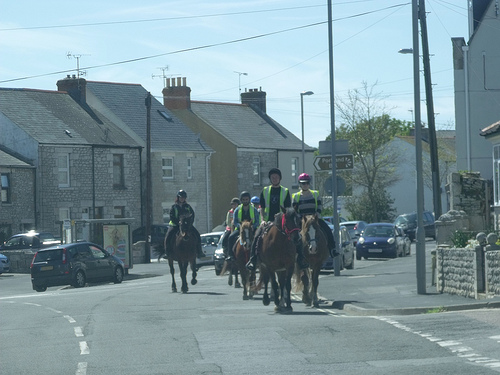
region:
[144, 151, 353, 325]
people riding horses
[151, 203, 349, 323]
horses walking down the road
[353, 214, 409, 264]
car on the side of the street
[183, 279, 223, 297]
shadow from the horse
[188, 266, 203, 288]
back leg is in the air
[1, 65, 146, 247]
the building is made of stone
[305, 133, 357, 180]
signs on a pole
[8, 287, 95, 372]
white dotted line on the street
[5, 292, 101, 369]
line is curving around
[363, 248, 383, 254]
license plate on front of the vehicle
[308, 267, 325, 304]
leg of a horse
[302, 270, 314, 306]
leg of a horse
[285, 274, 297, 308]
leg of a horse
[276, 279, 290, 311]
leg of a horse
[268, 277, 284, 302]
leg of a horse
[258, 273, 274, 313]
leg of a horse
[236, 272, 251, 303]
leg of a horse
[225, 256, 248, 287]
leg of a horse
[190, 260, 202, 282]
leg of a horse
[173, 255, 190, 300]
leg of a horse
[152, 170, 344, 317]
men riding on horses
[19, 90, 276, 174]
houses in the pack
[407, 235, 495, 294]
brick wall on side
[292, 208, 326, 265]
head of the horse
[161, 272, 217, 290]
feet of the horse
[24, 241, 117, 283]
back of the car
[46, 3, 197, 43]
sky is mostly clear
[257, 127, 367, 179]
signs on the pole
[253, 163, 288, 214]
vest on the man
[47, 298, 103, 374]
white lines on street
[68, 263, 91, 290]
the wheel of a car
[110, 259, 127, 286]
the wheel of a car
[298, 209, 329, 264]
a head of a horse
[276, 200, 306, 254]
a head of a horse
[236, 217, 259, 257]
a head of a horse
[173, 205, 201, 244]
a head of a horse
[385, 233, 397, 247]
the headlight of a car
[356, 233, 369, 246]
a head of a horse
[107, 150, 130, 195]
the window of a building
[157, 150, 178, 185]
the window of a building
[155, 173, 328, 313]
several people riding horses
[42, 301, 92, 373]
white lines painted on a street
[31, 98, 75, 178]
a building with a shingled roof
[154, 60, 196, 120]
a chimney on top of a roof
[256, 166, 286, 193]
a man wearing a black helmet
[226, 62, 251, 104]
a antenna on a roof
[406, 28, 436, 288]
a tall metal pole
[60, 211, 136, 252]
a bus stop shelter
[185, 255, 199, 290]
a horse with a foot raised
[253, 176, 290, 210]
a person wearing a safety vest